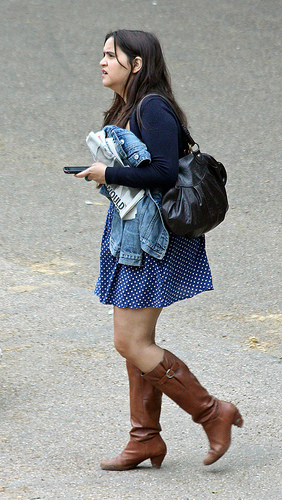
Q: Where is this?
A: This is at the sidewalk.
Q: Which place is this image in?
A: It is at the sidewalk.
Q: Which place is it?
A: It is a sidewalk.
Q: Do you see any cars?
A: No, there are no cars.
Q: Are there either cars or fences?
A: No, there are no cars or fences.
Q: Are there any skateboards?
A: No, there are no skateboards.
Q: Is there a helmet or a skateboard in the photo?
A: No, there are no skateboards or helmets.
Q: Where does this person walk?
A: The person walks on the sidewalk.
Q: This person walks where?
A: The person walks on the sidewalk.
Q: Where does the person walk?
A: The person walks on the sidewalk.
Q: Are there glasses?
A: No, there are no glasses.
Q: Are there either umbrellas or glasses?
A: No, there are no glasses or umbrellas.